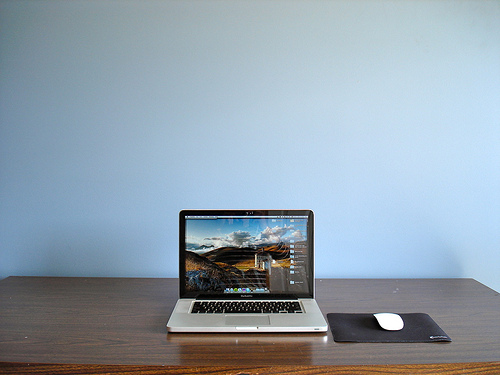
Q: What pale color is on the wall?
A: Light blue.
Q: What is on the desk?
A: A computer.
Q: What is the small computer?
A: A laptop.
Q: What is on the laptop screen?
A: Mountains and clouds.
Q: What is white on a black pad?
A: White mouse.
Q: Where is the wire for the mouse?
A: It is wireless.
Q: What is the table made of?
A: Wood.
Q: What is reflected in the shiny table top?
A: Bottom of the laptop.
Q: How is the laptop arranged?
A: It is open.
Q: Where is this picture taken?
A: An office.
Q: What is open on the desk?
A: A computer.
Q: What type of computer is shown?
A: Laptop.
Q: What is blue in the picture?
A: A wall.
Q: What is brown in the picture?
A: A desk.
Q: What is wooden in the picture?
A: Desk.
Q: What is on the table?
A: A computer.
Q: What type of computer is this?
A: A laptop.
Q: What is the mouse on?
A: A mousepad.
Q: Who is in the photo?
A: No one.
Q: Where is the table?
A: By the wall.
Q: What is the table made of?
A: Wood.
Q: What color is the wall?
A: Blue.